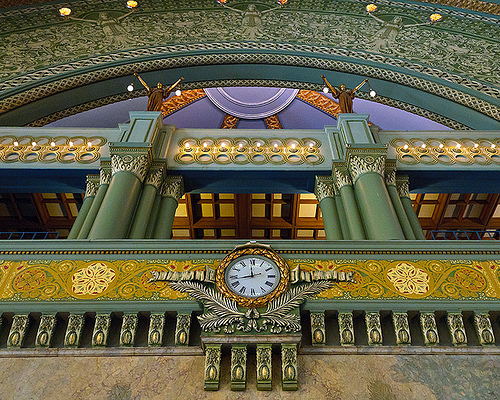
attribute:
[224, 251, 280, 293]
frame — gold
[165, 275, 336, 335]
leaves — golden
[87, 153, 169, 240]
columns —  green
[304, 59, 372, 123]
statue — brass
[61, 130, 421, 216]
trim — gold 